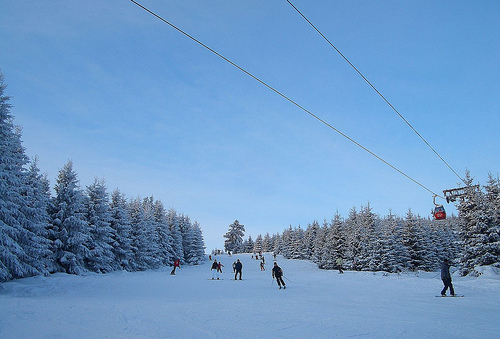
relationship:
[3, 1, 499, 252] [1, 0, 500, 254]
clouds in sky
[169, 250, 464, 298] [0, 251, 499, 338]
people on top of slope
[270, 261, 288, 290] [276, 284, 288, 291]
man wearing skis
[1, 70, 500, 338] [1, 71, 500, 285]
snow covering trees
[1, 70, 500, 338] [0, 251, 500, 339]
snow on top of slope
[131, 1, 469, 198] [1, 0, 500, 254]
cables in sky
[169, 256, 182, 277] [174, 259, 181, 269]
person wearing jacket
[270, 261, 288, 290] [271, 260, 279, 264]
man wearing hat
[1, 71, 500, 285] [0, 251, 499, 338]
trees on top of slope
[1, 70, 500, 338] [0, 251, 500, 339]
snow covering slope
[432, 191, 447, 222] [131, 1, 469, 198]
ski lift hanging on cables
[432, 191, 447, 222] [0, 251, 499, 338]
ski lift above slope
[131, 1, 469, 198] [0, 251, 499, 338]
cables above slope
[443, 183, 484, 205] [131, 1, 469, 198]
ski lift pole holding cables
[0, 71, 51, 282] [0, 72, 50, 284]
snow covering tree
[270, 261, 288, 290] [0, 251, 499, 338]
man skiing on slope